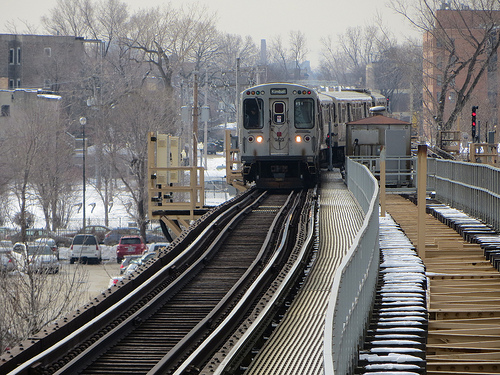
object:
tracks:
[5, 188, 314, 375]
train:
[238, 82, 387, 189]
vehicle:
[116, 235, 148, 264]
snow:
[0, 151, 236, 235]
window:
[243, 98, 264, 130]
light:
[256, 136, 262, 143]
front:
[236, 82, 320, 189]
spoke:
[229, 133, 239, 170]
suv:
[68, 233, 103, 264]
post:
[146, 131, 218, 220]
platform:
[351, 204, 426, 375]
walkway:
[354, 186, 500, 375]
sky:
[0, 0, 500, 75]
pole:
[78, 116, 86, 234]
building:
[422, 9, 500, 162]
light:
[472, 113, 476, 125]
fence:
[323, 156, 500, 375]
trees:
[0, 93, 182, 243]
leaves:
[0, 96, 75, 208]